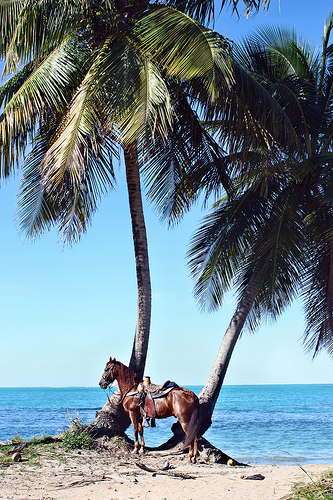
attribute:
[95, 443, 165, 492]
sand — brown, dry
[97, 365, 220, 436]
horse — standing, grown, big, adult, beautiful, brown, calm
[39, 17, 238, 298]
tree — palm, tall, green, brown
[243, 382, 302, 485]
water — perfect, calm, blue, clear, smooth, close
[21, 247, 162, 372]
sky — blue, light, bright, clear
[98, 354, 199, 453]
horse —  brown